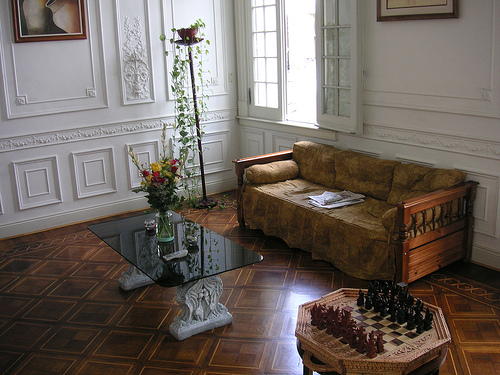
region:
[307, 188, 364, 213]
paper on the couch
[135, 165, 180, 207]
flowers on the table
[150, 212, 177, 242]
a vase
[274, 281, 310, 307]
light on the wooden floor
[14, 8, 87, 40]
a picture on the wall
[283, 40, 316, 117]
a window that is open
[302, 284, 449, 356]
a chess set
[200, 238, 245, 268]
a glass table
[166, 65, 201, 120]
leaves on the tree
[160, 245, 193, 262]
controller on the glass table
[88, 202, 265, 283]
Solid black reflecting table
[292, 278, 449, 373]
Brown and white checkered table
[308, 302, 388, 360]
Brown chess piece on table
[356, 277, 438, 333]
Black chess pieces on table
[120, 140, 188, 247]
Vase of colorful flowers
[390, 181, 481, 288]
Brown wooden right arm rest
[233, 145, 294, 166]
Brown wooden left arm rest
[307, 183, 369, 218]
Pile of white paper on couch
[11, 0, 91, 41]
Brown picture frame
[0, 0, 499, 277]
Beautiful majestic white walls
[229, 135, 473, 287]
the couch is against the wall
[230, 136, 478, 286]
the couch frame is made of wood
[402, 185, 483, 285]
the frame is brown in color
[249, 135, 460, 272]
the couch is made of fabric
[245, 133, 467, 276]
the upholstery is brown in color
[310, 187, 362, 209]
paper is on the couch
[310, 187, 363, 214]
the paper is white in color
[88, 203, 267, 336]
a coffee table is in front of the couch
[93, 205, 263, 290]
a glass top is on the base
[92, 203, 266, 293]
the glass top is dark in color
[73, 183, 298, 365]
a nice table with a black top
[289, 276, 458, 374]
a wooden chest set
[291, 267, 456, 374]
the chess set is shaped like an octagon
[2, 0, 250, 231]
there is molding on the white wall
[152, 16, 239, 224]
an elevated house plant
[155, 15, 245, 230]
the house plant has long vines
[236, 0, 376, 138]
the window is open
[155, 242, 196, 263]
a grey remote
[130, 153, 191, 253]
a glass vase filled with a bouquet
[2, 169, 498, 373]
the wooden floor has a square pattern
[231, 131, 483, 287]
Brown sofa in the living room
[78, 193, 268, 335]
Glasstop coffee table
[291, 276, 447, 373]
Chess table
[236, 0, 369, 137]
Glass window with white shutters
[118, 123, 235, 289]
Fresh flower arrangement on the coffee table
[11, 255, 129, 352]
Brown floor tiles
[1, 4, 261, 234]
Beautiful white wooden wall panels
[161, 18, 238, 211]
Creeper plant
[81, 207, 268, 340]
Coffee table with stone base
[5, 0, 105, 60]
Picture frame on the wall